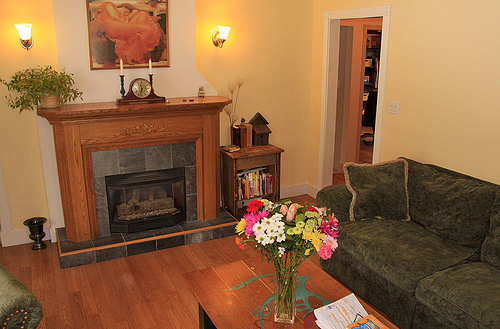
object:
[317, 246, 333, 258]
flowers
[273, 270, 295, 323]
vase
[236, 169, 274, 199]
books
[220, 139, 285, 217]
shelf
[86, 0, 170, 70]
painting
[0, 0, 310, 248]
wall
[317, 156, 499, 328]
couch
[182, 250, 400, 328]
table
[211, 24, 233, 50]
lamp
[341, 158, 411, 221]
pillow